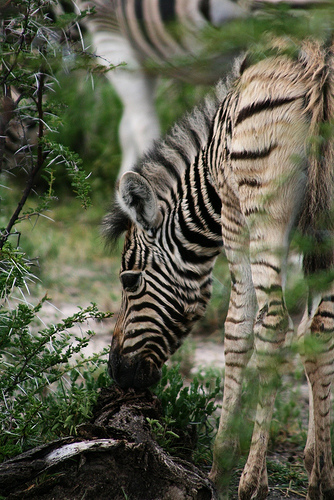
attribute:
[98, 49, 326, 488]
zebra — baby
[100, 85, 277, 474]
zebra — baby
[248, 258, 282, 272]
stripe — black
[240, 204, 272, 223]
stripe — black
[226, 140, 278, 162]
stripe — black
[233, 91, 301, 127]
stripe — black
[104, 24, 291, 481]
zebra — baby, small, skinny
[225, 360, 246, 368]
stripe — black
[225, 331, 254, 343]
stripe — black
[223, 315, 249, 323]
stripe — black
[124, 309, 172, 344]
stripe — black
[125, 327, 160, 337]
stripe — black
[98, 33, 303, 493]
zebra — small, young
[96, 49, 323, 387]
zebra — brown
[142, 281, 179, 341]
stripes — black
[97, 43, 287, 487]
zebra — baby, small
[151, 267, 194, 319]
stripes — multi-colored